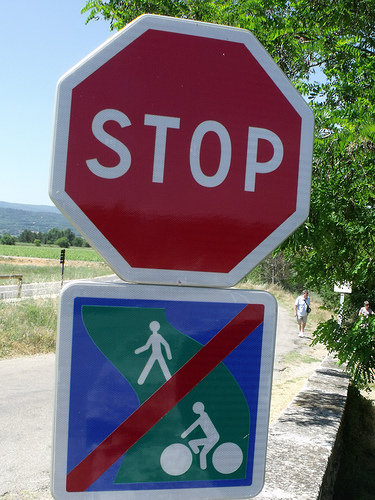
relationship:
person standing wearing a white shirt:
[295, 287, 309, 343] [294, 292, 306, 318]